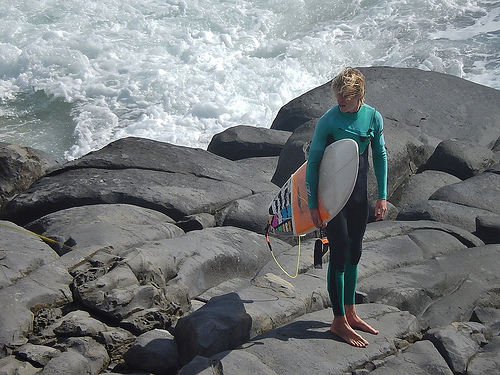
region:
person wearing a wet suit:
[258, 61, 405, 351]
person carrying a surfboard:
[248, 66, 407, 351]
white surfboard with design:
[250, 128, 361, 263]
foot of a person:
[329, 311, 370, 355]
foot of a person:
[343, 301, 383, 340]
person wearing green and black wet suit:
[299, 68, 398, 346]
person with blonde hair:
[257, 63, 402, 353]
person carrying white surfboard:
[252, 58, 410, 346]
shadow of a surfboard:
[109, 288, 261, 374]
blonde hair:
[327, 65, 369, 100]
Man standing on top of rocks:
[302, 61, 388, 348]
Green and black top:
[305, 104, 383, 201]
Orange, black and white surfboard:
[264, 138, 359, 238]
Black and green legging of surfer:
[330, 221, 372, 316]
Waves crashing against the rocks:
[6, 5, 493, 157]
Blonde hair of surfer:
[330, 68, 365, 101]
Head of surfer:
[332, 69, 367, 122]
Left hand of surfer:
[370, 193, 390, 220]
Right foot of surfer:
[327, 320, 367, 347]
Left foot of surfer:
[342, 311, 378, 336]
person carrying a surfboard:
[234, 57, 424, 373]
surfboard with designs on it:
[254, 139, 371, 253]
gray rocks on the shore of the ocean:
[43, 182, 230, 331]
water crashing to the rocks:
[34, 28, 261, 183]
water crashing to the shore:
[29, 34, 279, 146]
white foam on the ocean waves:
[42, 29, 259, 125]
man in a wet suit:
[306, 67, 406, 362]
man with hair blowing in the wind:
[249, 48, 426, 373]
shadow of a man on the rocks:
[94, 279, 319, 367]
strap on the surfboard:
[256, 228, 316, 288]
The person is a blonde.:
[313, 65, 381, 117]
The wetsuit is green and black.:
[308, 95, 391, 347]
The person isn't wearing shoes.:
[318, 312, 385, 352]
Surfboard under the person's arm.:
[253, 126, 373, 239]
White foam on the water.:
[61, 61, 283, 126]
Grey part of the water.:
[15, 110, 65, 144]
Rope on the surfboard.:
[262, 227, 316, 280]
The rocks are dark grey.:
[24, 173, 267, 370]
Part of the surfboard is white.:
[320, 136, 362, 206]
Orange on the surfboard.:
[286, 170, 327, 233]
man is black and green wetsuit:
[297, 61, 388, 351]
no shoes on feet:
[324, 310, 384, 350]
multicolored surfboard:
[264, 136, 362, 276]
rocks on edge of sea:
[36, 72, 339, 208]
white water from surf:
[46, 39, 214, 114]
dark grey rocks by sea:
[402, 89, 462, 123]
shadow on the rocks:
[126, 274, 273, 374]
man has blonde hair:
[330, 63, 372, 113]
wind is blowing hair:
[325, 65, 373, 119]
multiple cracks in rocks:
[395, 207, 478, 373]